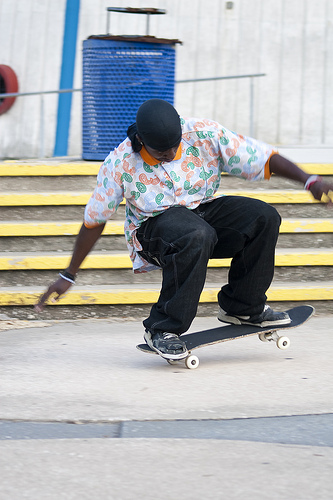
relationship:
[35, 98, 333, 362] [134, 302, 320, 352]
guy on board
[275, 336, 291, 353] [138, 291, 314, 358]
wheel on skateboard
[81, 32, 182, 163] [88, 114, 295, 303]
trash can behind skater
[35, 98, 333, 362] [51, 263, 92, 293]
guy wearing bracelets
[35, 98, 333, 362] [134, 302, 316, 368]
guy riding board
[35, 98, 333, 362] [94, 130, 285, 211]
guy wearing shirt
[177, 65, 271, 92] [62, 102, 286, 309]
railing behind skater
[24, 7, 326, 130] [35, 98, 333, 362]
building behind guy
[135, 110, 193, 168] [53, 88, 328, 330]
head of man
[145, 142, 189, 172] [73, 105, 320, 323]
face of man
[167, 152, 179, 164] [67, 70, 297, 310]
nose of man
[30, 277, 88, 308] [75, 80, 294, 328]
hand of man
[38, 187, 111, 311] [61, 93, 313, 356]
arm of man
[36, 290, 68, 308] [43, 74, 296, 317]
fingers of man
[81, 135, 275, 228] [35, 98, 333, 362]
shirt on guy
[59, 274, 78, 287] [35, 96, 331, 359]
bracelet on boy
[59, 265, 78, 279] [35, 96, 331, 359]
bracelet on boy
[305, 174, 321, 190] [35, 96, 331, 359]
bracelet on boy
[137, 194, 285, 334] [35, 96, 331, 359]
jeans on boy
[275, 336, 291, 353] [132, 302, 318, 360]
wheel on skateboard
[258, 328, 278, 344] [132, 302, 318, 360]
wheel on skateboard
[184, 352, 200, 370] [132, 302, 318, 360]
wheel on skateboard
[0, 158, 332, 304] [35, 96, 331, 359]
steps behind boy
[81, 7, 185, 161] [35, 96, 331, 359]
trash can behind boy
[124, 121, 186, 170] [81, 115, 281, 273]
collar on shirt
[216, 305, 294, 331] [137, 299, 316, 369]
shoe on skateboard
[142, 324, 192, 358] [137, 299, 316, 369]
shoe on skateboard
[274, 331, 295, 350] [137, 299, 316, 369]
wheel on skateboard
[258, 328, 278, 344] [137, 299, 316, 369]
wheel on skateboard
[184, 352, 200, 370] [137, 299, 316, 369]
wheel on skateboard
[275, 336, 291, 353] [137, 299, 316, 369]
wheel on skateboard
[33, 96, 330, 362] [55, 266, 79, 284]
guy wearing bracelet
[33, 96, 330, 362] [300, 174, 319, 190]
guy wearing bracelet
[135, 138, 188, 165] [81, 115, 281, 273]
collar on shirt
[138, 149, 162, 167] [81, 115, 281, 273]
collar on shirt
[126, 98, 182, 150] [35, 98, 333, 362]
durag on guy